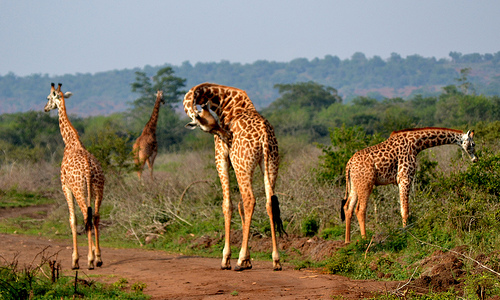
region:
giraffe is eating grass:
[334, 116, 489, 250]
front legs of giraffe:
[393, 180, 415, 233]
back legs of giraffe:
[342, 185, 374, 250]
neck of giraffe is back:
[168, 75, 264, 147]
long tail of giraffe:
[259, 134, 291, 248]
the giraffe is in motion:
[39, 70, 116, 280]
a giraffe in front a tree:
[125, 58, 187, 188]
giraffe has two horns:
[47, 77, 64, 90]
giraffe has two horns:
[190, 98, 214, 129]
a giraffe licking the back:
[166, 72, 288, 274]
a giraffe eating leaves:
[319, 126, 491, 246]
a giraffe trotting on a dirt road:
[29, 84, 119, 281]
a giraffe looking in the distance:
[119, 72, 186, 194]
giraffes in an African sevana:
[26, 57, 485, 287]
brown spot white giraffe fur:
[234, 156, 247, 166]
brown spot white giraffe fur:
[368, 167, 373, 177]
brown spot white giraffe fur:
[65, 133, 70, 139]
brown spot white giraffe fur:
[146, 137, 148, 144]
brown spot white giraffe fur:
[423, 133, 439, 141]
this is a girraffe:
[0, 68, 116, 288]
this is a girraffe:
[178, 69, 289, 269]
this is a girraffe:
[342, 112, 482, 242]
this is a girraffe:
[106, 80, 183, 182]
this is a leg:
[56, 197, 83, 278]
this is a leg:
[216, 156, 236, 268]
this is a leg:
[233, 169, 258, 274]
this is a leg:
[257, 170, 284, 287]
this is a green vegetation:
[331, 233, 443, 281]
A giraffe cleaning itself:
[181, 81, 291, 271]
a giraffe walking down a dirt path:
[38, 80, 110, 272]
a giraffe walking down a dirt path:
[131, 85, 166, 189]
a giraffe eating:
[336, 123, 477, 246]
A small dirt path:
[0, 199, 402, 299]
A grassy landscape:
[0, 131, 499, 298]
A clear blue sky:
[0, 1, 499, 75]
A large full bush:
[315, 120, 431, 185]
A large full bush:
[90, 123, 143, 189]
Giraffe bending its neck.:
[183, 77, 288, 270]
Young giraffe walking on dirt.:
[39, 82, 106, 268]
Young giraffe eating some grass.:
[333, 119, 477, 246]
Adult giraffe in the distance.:
[124, 88, 171, 184]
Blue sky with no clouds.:
[0, 1, 498, 78]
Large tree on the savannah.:
[130, 65, 190, 162]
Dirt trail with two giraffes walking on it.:
[0, 231, 455, 298]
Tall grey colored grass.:
[2, 138, 499, 236]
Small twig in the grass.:
[45, 257, 65, 284]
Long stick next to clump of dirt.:
[407, 227, 499, 279]